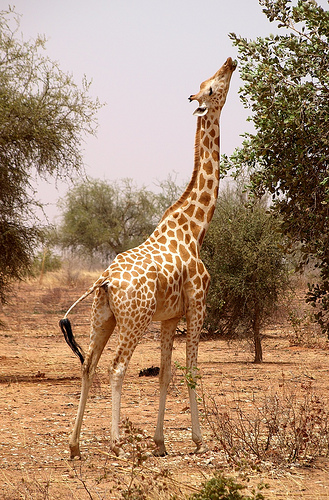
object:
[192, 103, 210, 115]
ear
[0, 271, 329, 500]
field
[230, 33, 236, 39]
leaves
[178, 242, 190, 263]
spots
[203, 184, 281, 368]
trees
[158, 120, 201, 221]
mane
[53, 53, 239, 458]
giraffe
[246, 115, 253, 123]
leaves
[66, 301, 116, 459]
leg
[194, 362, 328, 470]
branches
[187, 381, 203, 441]
white leg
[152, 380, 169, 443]
white leg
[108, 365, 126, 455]
white leg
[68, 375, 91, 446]
white leg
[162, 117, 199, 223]
fringe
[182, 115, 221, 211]
neck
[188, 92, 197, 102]
horns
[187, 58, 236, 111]
head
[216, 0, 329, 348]
tree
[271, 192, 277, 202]
leaves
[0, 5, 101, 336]
trees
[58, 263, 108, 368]
skinny tail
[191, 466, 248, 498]
bush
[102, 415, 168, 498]
bush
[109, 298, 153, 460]
leg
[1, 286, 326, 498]
dirt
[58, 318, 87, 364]
hair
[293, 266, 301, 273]
leaves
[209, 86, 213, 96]
eye